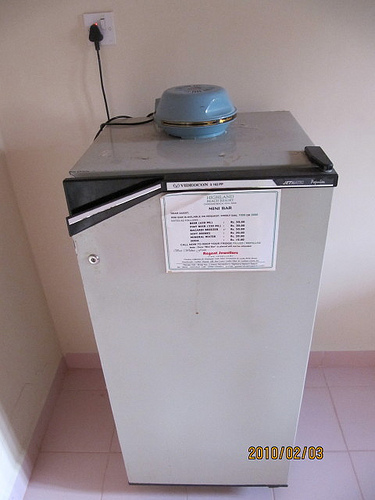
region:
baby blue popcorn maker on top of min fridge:
[142, 68, 244, 144]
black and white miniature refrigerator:
[65, 158, 326, 483]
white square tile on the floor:
[56, 436, 111, 498]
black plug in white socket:
[82, 15, 108, 49]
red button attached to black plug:
[95, 20, 100, 28]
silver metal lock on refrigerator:
[81, 246, 109, 269]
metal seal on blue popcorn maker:
[181, 118, 226, 128]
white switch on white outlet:
[99, 14, 108, 32]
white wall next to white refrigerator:
[6, 278, 49, 385]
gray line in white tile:
[326, 401, 360, 451]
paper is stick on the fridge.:
[151, 185, 288, 288]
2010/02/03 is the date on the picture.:
[245, 439, 326, 479]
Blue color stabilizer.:
[147, 81, 237, 143]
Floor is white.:
[328, 409, 369, 454]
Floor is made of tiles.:
[323, 393, 367, 464]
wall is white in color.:
[10, 227, 63, 323]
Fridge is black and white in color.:
[52, 160, 337, 498]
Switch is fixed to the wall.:
[73, 12, 131, 73]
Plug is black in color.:
[84, 14, 123, 65]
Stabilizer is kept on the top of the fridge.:
[149, 80, 241, 174]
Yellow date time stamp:
[246, 444, 321, 459]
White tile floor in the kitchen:
[25, 347, 372, 498]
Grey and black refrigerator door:
[62, 173, 344, 486]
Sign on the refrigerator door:
[158, 191, 281, 273]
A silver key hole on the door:
[85, 253, 100, 265]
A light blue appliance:
[150, 80, 240, 142]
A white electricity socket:
[81, 10, 119, 48]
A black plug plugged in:
[89, 24, 103, 51]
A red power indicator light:
[94, 21, 99, 26]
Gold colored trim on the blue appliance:
[158, 114, 238, 130]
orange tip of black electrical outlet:
[84, 21, 101, 32]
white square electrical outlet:
[78, 5, 128, 52]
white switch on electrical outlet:
[98, 16, 111, 31]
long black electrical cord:
[79, 23, 124, 126]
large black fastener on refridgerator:
[298, 139, 338, 176]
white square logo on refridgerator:
[165, 174, 293, 288]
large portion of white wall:
[192, 24, 351, 70]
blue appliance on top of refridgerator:
[134, 80, 252, 151]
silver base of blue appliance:
[181, 121, 226, 129]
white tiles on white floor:
[37, 438, 105, 476]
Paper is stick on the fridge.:
[150, 166, 288, 293]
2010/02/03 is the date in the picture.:
[247, 440, 338, 470]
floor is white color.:
[321, 417, 365, 483]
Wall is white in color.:
[2, 228, 66, 334]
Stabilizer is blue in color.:
[149, 91, 230, 134]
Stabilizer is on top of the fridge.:
[156, 86, 236, 158]